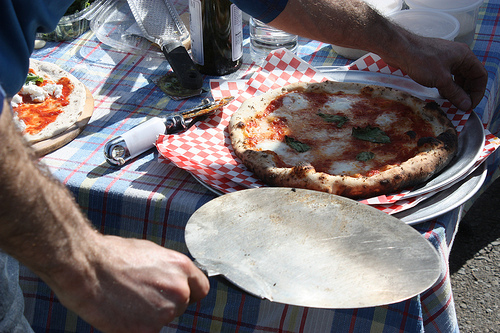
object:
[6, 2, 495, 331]
tablecloth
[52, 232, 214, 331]
hand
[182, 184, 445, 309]
tray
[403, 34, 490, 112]
hand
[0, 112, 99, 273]
arm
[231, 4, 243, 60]
white label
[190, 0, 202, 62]
white label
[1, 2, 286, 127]
shirt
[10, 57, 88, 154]
pizza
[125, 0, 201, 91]
grater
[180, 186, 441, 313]
pan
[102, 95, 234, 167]
cutter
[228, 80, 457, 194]
pizza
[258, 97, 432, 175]
sauce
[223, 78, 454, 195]
pie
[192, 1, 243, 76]
bottle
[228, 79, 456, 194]
crust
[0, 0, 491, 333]
man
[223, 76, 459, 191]
pan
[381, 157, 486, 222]
pan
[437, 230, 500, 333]
wall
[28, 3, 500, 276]
table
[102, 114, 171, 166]
handle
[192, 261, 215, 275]
handle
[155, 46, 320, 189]
saviet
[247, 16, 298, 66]
water bottle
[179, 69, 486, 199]
pizza pan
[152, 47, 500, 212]
paper